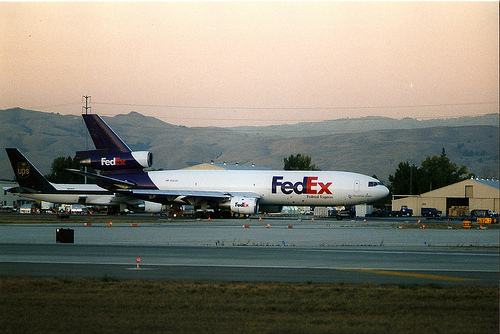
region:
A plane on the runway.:
[78, 118, 410, 228]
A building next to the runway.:
[370, 159, 497, 225]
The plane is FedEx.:
[257, 161, 328, 204]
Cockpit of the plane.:
[358, 166, 382, 190]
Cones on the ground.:
[121, 207, 375, 229]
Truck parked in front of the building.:
[386, 197, 425, 225]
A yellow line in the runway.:
[366, 256, 468, 281]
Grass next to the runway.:
[96, 272, 392, 331]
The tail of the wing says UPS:
[6, 139, 61, 194]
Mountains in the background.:
[125, 112, 483, 164]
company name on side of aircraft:
[266, 167, 338, 202]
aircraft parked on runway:
[16, 103, 407, 242]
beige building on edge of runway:
[381, 167, 498, 217]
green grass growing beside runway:
[13, 276, 428, 331]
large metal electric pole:
[76, 88, 97, 114]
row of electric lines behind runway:
[85, 94, 499, 122]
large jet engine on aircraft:
[78, 133, 159, 175]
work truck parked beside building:
[383, 201, 421, 218]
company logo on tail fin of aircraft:
[8, 154, 41, 184]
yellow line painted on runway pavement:
[328, 257, 480, 284]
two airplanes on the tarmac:
[5, 111, 390, 218]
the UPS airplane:
[5, 145, 112, 205]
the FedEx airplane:
[66, 110, 391, 215]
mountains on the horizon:
[5, 107, 499, 188]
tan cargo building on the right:
[392, 176, 494, 214]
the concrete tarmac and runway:
[2, 223, 497, 284]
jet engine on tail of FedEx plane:
[76, 150, 152, 172]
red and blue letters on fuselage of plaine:
[271, 175, 333, 197]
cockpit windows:
[370, 181, 380, 186]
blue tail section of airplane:
[69, 112, 156, 214]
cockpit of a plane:
[355, 160, 392, 207]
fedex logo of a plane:
[265, 170, 348, 212]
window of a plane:
[362, 170, 388, 187]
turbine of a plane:
[227, 188, 272, 216]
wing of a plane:
[77, 88, 139, 159]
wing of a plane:
[6, 137, 56, 187]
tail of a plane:
[100, 148, 195, 215]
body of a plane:
[182, 153, 313, 210]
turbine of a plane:
[132, 135, 159, 162]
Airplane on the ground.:
[66, 103, 388, 217]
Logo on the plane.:
[263, 170, 337, 202]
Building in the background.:
[388, 167, 498, 219]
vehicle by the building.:
[466, 206, 498, 221]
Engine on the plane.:
[220, 193, 265, 213]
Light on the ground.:
[129, 253, 146, 269]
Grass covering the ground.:
[4, 272, 497, 332]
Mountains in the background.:
[0, 97, 498, 184]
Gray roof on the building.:
[463, 173, 498, 191]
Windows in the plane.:
[362, 178, 384, 191]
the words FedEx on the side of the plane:
[264, 172, 339, 202]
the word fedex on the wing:
[86, 151, 136, 170]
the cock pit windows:
[364, 177, 387, 191]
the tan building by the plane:
[388, 175, 497, 218]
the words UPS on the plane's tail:
[9, 162, 35, 185]